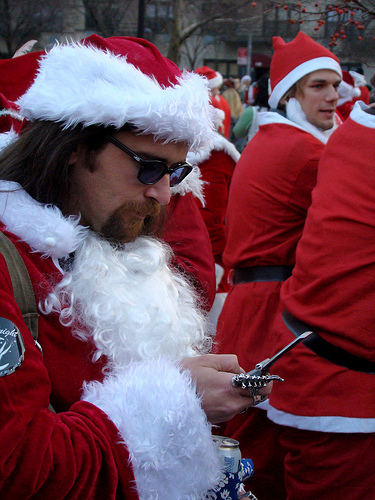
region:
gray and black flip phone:
[236, 327, 313, 392]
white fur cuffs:
[74, 355, 227, 499]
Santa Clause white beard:
[44, 226, 210, 363]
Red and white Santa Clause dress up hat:
[0, 32, 204, 152]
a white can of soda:
[205, 432, 247, 495]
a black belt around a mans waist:
[227, 265, 306, 284]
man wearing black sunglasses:
[88, 124, 193, 187]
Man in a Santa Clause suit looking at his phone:
[0, 30, 310, 496]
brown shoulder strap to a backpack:
[0, 231, 48, 355]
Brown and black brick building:
[0, 1, 374, 77]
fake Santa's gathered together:
[17, 11, 349, 281]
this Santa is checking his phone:
[108, 155, 324, 423]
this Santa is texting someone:
[80, 132, 314, 386]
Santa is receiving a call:
[115, 153, 319, 395]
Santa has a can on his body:
[209, 430, 250, 484]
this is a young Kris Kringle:
[265, 33, 352, 133]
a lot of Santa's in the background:
[200, 27, 275, 134]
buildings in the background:
[17, 4, 356, 40]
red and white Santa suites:
[131, 36, 373, 257]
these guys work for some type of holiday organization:
[16, 17, 363, 270]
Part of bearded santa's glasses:
[134, 153, 193, 187]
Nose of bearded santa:
[145, 172, 172, 208]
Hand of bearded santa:
[176, 340, 274, 424]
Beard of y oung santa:
[103, 200, 163, 247]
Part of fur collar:
[7, 189, 74, 259]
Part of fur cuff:
[114, 383, 201, 467]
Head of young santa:
[263, 26, 341, 129]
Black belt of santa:
[229, 259, 289, 279]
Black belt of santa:
[274, 304, 373, 384]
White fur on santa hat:
[54, 59, 126, 102]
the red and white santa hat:
[2, 40, 221, 142]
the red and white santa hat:
[192, 64, 222, 87]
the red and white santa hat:
[269, 30, 338, 102]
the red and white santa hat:
[336, 70, 353, 96]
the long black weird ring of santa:
[234, 373, 281, 389]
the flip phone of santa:
[235, 330, 315, 376]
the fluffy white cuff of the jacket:
[86, 370, 224, 497]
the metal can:
[210, 434, 242, 478]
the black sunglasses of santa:
[109, 133, 193, 189]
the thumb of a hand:
[187, 353, 244, 374]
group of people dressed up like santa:
[2, 16, 374, 482]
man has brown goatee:
[101, 195, 170, 249]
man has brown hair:
[0, 113, 123, 204]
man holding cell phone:
[160, 313, 326, 426]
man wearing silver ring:
[218, 359, 288, 398]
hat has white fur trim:
[0, 18, 237, 163]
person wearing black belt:
[268, 291, 368, 376]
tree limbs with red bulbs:
[251, 0, 373, 54]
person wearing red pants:
[259, 399, 373, 496]